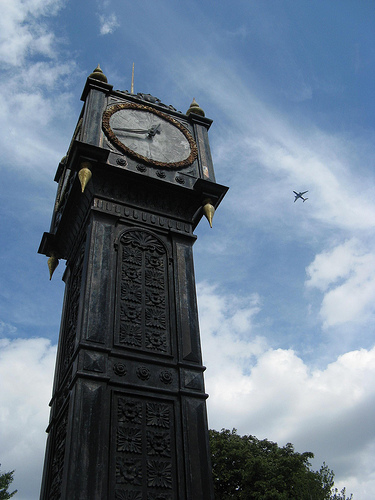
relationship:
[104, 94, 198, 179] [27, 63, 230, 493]
face on clock tower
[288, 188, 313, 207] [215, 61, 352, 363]
airplane flying in sky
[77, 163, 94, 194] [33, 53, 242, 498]
decorative spikes atop clock tower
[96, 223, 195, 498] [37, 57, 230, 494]
ornate designs on side of tower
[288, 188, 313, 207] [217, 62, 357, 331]
airplane flying high in air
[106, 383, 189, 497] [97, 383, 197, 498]
etched pattern on stone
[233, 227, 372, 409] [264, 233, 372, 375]
sky with white clouds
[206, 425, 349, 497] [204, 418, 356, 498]
bushy section of leaves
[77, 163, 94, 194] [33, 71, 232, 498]
decorative spikes on clock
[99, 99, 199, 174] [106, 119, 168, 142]
clock with two hands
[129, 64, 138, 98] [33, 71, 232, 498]
antennae at top of clock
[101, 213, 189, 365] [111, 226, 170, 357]
small section of ornate designs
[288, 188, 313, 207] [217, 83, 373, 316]
airplane in sky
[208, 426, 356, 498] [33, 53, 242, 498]
tree behind clock tower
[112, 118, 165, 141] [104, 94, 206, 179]
black hands on face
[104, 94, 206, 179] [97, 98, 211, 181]
face of clock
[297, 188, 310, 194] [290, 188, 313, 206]
wing of airplane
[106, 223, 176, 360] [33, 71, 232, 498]
pattern on clock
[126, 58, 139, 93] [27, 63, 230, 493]
pole on clock tower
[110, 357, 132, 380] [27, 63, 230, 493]
rosette on clock tower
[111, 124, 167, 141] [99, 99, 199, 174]
hands of clock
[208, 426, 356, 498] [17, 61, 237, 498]
tree on side clock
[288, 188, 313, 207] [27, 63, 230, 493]
airplane over clock tower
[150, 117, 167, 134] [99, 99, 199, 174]
hands on clock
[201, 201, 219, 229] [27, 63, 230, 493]
object on clock tower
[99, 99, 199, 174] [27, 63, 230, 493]
clock on clock tower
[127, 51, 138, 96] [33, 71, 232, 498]
lighting rod on clock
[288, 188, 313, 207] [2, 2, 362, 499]
airplane flying through sky